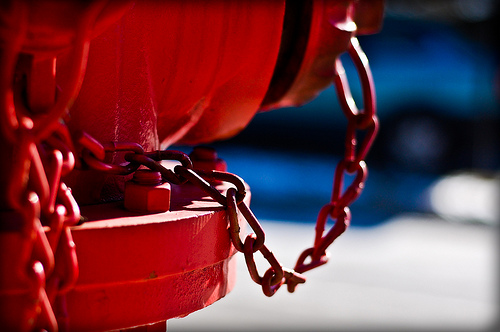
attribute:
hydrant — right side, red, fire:
[5, 7, 377, 318]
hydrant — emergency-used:
[14, 36, 346, 316]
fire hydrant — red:
[5, 2, 397, 327]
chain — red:
[5, 2, 404, 328]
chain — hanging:
[198, 155, 412, 277]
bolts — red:
[114, 158, 189, 218]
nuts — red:
[103, 155, 234, 238]